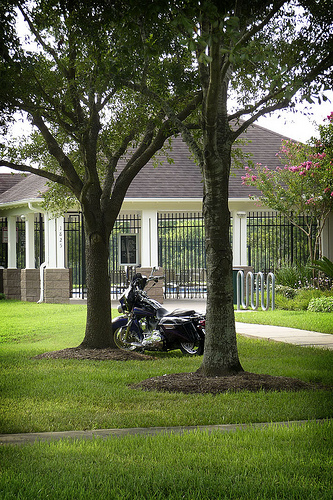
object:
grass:
[0, 283, 332, 500]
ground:
[0, 294, 332, 499]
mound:
[132, 371, 313, 393]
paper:
[163, 373, 167, 376]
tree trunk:
[121, 3, 333, 165]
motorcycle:
[113, 263, 206, 355]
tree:
[107, 0, 332, 375]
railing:
[236, 270, 275, 310]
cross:
[94, 235, 98, 243]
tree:
[0, 0, 201, 350]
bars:
[64, 212, 319, 300]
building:
[0, 94, 333, 303]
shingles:
[2, 113, 332, 198]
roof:
[0, 113, 332, 203]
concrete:
[163, 296, 333, 354]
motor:
[135, 297, 149, 307]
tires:
[114, 324, 143, 351]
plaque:
[121, 236, 135, 263]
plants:
[275, 255, 333, 288]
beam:
[44, 208, 65, 269]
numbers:
[59, 226, 62, 247]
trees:
[0, 0, 333, 404]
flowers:
[295, 271, 331, 290]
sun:
[0, 301, 328, 348]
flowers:
[241, 111, 333, 207]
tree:
[241, 112, 333, 286]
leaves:
[0, 0, 333, 222]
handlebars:
[133, 264, 165, 311]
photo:
[1, 1, 333, 498]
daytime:
[0, 2, 333, 170]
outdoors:
[2, 2, 332, 498]